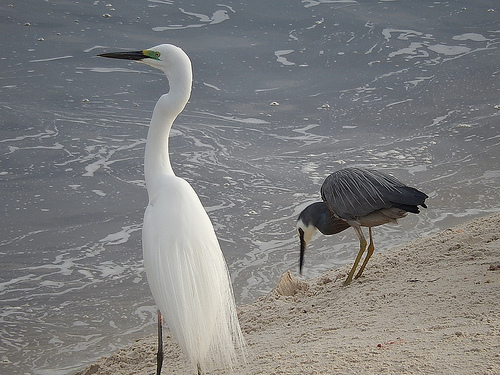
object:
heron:
[88, 38, 260, 375]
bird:
[289, 163, 432, 289]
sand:
[36, 212, 500, 375]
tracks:
[316, 318, 347, 333]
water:
[2, 3, 498, 375]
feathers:
[141, 64, 166, 229]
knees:
[357, 237, 370, 253]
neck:
[140, 84, 192, 184]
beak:
[93, 47, 151, 66]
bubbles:
[339, 123, 359, 131]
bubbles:
[265, 40, 299, 71]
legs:
[147, 303, 169, 375]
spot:
[142, 48, 163, 61]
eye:
[153, 50, 162, 58]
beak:
[296, 238, 307, 277]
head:
[90, 42, 197, 96]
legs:
[341, 219, 369, 288]